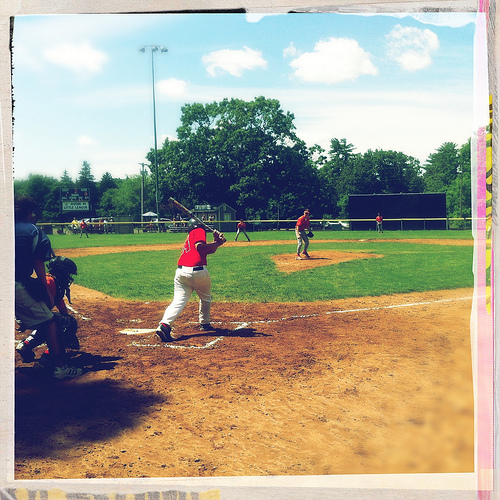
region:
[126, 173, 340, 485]
man in red shirt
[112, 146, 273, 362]
man in red shirt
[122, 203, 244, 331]
man playing a game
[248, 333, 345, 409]
brown dirt under batter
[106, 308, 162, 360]
home plate next to batter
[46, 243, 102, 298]
mask of the catcher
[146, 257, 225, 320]
white pants on player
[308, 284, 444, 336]
first base line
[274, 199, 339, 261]
pitcher on the mound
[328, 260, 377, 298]
gren grass next to pitcher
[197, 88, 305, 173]
trees behind the players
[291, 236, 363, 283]
mound below the pitcher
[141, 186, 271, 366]
This is a batter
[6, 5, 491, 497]
This is a photograph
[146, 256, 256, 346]
He has white pants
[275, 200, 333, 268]
The pitcher right here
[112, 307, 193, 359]
Home base in the front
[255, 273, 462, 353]
The white paint is a path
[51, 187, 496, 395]
The grass has been cut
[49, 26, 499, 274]
It is sunny outside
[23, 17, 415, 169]
Clouds are in the distance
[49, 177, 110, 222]
The sign has game information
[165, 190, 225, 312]
baseball player holding bat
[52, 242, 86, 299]
baseball player wearing catchers mask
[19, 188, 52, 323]
umpire of baseball game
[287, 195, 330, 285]
pitcher of baseball game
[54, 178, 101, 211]
score board at baseball game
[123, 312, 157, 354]
home plate at baseball game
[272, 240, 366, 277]
pitchers mound at baseball game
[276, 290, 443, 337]
white line on baseball field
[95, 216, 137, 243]
people watching baseball game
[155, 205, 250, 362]
player wearing a red shirt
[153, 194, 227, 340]
batter with red and white uniform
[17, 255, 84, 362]
catcher wearing red and white uniform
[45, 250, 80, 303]
black catcher's helmet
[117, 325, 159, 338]
white home plate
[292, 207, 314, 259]
pitcher on the pitcher's man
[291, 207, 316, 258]
pitcher wearing a red and white uniform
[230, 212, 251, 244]
short stop playing on the field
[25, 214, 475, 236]
fence around the field with yellow top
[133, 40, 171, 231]
metal pole with lights on top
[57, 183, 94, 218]
white and black baseball scoreboard